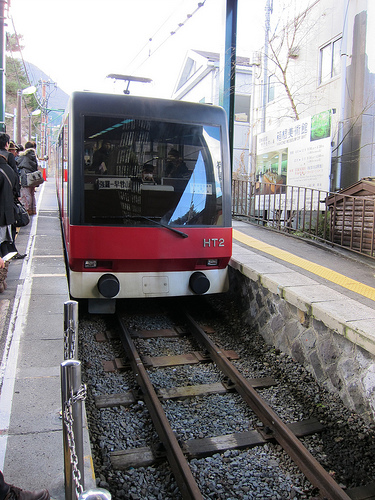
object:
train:
[55, 90, 232, 314]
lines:
[2, 181, 50, 472]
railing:
[233, 172, 375, 263]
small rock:
[226, 472, 233, 480]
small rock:
[261, 443, 271, 455]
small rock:
[256, 418, 265, 426]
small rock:
[218, 409, 226, 419]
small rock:
[187, 375, 192, 381]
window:
[317, 32, 345, 89]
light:
[15, 87, 40, 150]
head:
[0, 133, 11, 151]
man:
[0, 149, 16, 262]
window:
[75, 110, 232, 229]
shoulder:
[20, 151, 28, 158]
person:
[8, 139, 16, 156]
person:
[30, 141, 36, 149]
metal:
[60, 300, 114, 498]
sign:
[252, 107, 337, 213]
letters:
[203, 238, 225, 247]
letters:
[275, 122, 308, 145]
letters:
[258, 135, 275, 146]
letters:
[289, 144, 323, 192]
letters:
[255, 194, 324, 209]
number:
[218, 238, 225, 247]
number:
[120, 180, 125, 188]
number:
[113, 179, 119, 188]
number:
[105, 179, 110, 188]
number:
[100, 181, 105, 189]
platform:
[1, 178, 69, 500]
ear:
[5, 141, 9, 148]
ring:
[60, 359, 81, 368]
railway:
[79, 294, 375, 499]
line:
[229, 219, 375, 302]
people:
[0, 132, 21, 244]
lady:
[15, 141, 45, 217]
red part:
[70, 227, 232, 267]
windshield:
[81, 114, 224, 230]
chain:
[58, 314, 87, 500]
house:
[318, 177, 375, 255]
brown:
[345, 198, 362, 232]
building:
[250, 0, 375, 261]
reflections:
[83, 117, 222, 229]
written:
[203, 236, 225, 247]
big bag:
[27, 170, 44, 187]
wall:
[253, 0, 368, 229]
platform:
[220, 205, 375, 428]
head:
[70, 89, 233, 315]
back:
[21, 148, 38, 188]